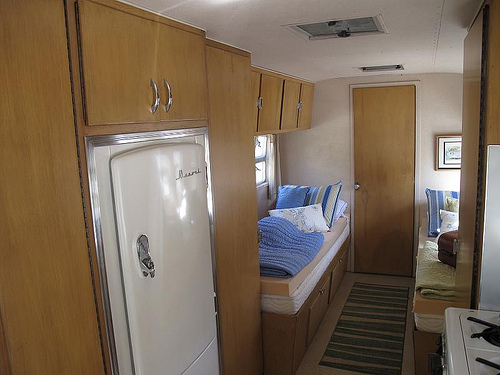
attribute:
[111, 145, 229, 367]
refrigerator door — white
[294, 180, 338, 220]
pillow — striped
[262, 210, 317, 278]
blanket — blue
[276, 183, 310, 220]
pillow — light blue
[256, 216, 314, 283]
blanket — light blue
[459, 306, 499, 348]
stove — white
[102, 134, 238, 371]
refrigerator — white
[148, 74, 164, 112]
handle — silver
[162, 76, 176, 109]
handle — silver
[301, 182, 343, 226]
pillow — blue, yellow, dark blue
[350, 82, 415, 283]
door — light brown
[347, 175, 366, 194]
door handle — silver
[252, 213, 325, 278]
blanket — blue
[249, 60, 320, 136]
cabinets — brown, wooden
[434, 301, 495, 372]
stove — white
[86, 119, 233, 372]
fridge — white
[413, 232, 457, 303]
blanket — folded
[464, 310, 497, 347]
burner — black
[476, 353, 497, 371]
burner — black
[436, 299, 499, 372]
stove — white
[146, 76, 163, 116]
handles — silver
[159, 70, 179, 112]
handles — silver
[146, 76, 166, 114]
hendge — small, metal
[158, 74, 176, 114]
hendge — small, metal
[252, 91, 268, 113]
hendge — small, metal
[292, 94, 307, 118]
hendge — small, metal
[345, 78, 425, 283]
door — shut, brown, wooden, closed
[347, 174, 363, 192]
handle — small, metal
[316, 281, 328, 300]
hendge — small, metal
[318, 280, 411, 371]
floor mat — colorful, small